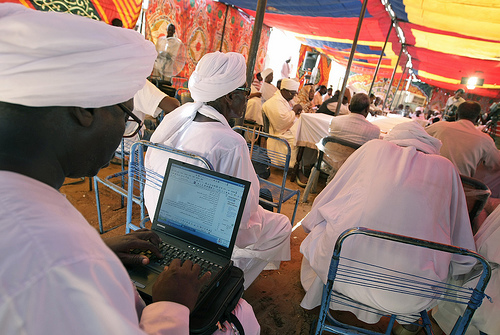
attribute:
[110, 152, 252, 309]
laptop — black, open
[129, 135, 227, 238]
chair — metal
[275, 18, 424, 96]
cloth — red, yellow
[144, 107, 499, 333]
chairs — blue metal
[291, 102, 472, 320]
man — slumped over